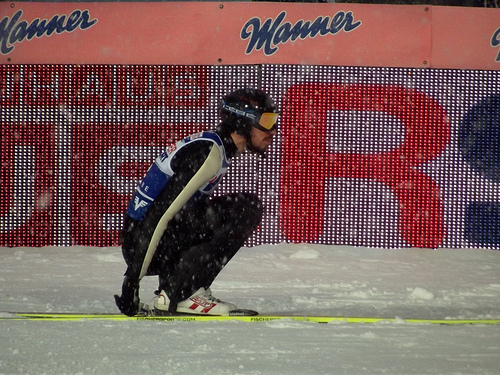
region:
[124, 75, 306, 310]
skier kneeling down on skis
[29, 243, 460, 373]
white snow and ice on ground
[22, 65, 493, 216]
digital read out sign in background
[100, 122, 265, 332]
snow suit on skier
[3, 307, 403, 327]
neon green skis in snow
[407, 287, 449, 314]
clumps of ice on ground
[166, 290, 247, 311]
white and red sneakers on skis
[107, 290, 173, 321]
black gloves on skier's hands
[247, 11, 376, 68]
manner written on orange wall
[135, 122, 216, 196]
blue sponser logos on back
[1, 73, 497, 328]
A man on skies croutched over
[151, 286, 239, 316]
The white shoes in the skies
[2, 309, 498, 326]
The yellow skies in the snow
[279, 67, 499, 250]
The led lights on the sign board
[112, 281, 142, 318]
The black glove of the man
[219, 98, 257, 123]
The white strap of the googles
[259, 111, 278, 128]
The yellow tint of the googles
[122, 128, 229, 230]
The blue and white vest on the skiier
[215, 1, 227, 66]
Rivets in the pink billboard advertisement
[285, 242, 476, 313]
Clumps of snow on the ground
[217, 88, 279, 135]
a ski jumper's ski helmet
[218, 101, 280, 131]
amber color lens on the ski goggles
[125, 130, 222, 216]
a blue and white competition vest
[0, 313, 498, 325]
long ski jumping snow skis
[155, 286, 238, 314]
ski jumping ski boot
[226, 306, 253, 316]
ski jumping boot binder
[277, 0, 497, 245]
advertising banner on the wall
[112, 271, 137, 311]
the skier has black ski gloves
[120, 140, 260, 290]
black and beige ski jumper suit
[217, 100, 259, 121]
the ski goggles strap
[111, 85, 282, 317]
A man in a squatting position.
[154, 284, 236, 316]
White tennis shoes with red accents.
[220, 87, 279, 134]
A helmet with goggles.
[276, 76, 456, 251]
A large capital R.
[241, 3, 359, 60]
The word Mammer in cursive letters.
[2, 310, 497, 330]
A long yellow object with black text.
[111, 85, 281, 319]
An athlete playing a sport.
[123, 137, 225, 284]
A black and white sleeve.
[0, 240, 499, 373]
A snow-covered ground.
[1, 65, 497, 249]
A wall with many colorful letters.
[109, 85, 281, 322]
man crouched down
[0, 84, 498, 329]
man crouched down on skis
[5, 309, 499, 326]
long yellow skis in snow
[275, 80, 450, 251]
large red colored R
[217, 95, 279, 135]
goggles around man's eyes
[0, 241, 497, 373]
white snow covered ground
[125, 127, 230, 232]
blue and white vest on man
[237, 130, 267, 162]
strap of helmet attached under chin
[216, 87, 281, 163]
a black helmet on head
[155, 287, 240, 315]
white ski boots with red stripes